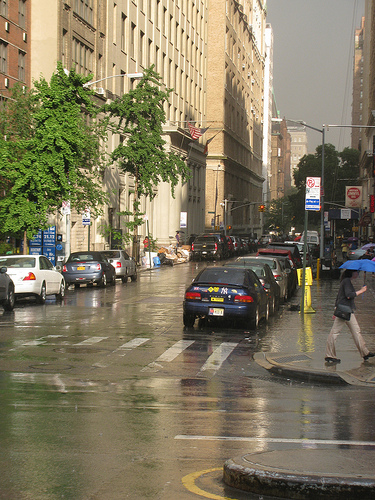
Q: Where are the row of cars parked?
A: At the curb.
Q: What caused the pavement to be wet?
A: Rain.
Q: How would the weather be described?
A: Rainy and overcast.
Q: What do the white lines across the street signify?
A: A crosswalk.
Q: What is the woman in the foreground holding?
A: An umbrella.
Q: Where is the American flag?
A: Above the large columns of the building on the left hand side of the photo.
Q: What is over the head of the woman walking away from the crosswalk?
A: An umbrella.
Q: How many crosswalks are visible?
A: One.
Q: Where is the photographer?
A: Facing the walker, on the other side of the median.